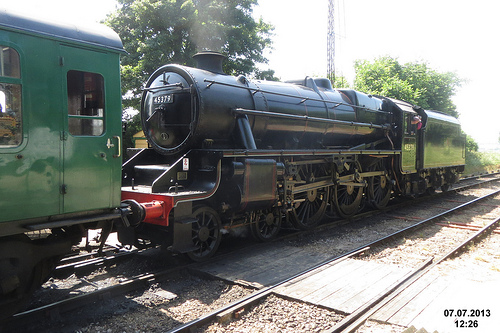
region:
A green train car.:
[0, 5, 122, 310]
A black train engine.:
[120, 1, 462, 263]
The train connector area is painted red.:
[119, 193, 174, 228]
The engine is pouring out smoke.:
[191, 1, 227, 73]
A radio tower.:
[324, 1, 336, 78]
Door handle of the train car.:
[105, 135, 114, 150]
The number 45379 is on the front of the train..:
[151, 94, 173, 103]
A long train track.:
[0, 170, 498, 332]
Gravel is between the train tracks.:
[168, 290, 350, 330]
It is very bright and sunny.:
[1, 1, 498, 151]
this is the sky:
[289, 4, 309, 51]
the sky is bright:
[282, 4, 310, 68]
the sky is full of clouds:
[278, 8, 302, 55]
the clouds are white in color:
[280, 10, 307, 65]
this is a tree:
[131, 2, 229, 48]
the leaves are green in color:
[141, 3, 244, 53]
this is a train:
[9, 16, 473, 206]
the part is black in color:
[176, 78, 246, 120]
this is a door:
[56, 37, 123, 216]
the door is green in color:
[68, 133, 97, 193]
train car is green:
[8, 29, 118, 209]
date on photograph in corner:
[440, 307, 490, 319]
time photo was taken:
[446, 319, 481, 330]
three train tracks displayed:
[203, 221, 494, 318]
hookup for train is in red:
[112, 191, 179, 230]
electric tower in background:
[317, 2, 351, 83]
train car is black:
[150, 82, 385, 145]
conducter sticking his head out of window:
[407, 114, 419, 143]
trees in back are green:
[358, 61, 458, 106]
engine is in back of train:
[382, 96, 482, 194]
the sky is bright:
[291, 8, 317, 58]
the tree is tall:
[137, 0, 256, 45]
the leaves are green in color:
[175, 5, 227, 32]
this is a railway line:
[78, 246, 138, 278]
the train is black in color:
[204, 95, 226, 135]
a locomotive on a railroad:
[0, 0, 482, 294]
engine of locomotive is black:
[122, 36, 402, 251]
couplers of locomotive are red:
[119, 178, 186, 253]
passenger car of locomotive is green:
[0, 0, 133, 257]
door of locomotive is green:
[59, 45, 128, 217]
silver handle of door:
[111, 125, 126, 165]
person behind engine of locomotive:
[384, 88, 442, 183]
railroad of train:
[53, 182, 498, 325]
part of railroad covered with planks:
[234, 240, 490, 330]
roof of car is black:
[5, 8, 137, 225]